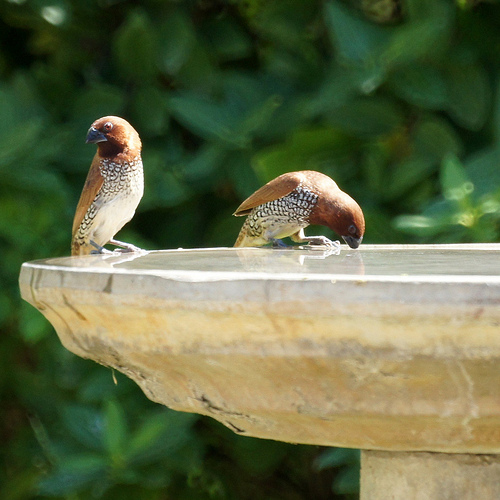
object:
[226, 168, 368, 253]
bird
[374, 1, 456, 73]
leaf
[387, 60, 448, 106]
leaf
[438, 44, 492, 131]
leaf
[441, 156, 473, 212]
leaf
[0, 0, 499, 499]
plants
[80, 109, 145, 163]
head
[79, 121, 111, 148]
beak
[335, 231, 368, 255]
beak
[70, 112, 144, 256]
bird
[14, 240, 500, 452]
birdbath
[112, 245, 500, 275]
water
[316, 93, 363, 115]
ground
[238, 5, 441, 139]
bushes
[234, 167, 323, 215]
wing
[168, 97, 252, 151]
leaf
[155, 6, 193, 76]
leaf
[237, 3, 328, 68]
leaf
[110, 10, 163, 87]
leaf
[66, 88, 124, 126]
leaf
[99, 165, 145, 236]
breast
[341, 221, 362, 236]
eye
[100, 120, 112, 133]
eye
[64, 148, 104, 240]
wing